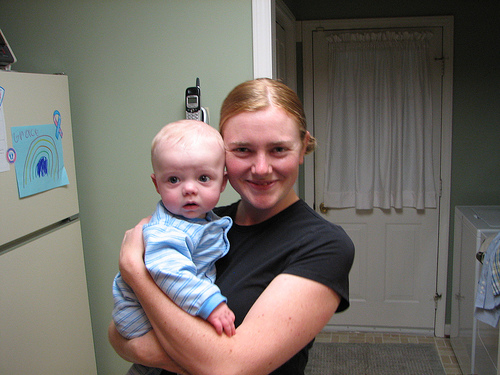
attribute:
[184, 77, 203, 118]
telephone — grey, landline, silver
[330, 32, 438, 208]
curtain — white, beige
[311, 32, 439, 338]
door — white, beige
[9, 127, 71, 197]
drawing — rainbow, blue, child's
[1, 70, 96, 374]
fridge — decorated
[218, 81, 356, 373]
woman — smiling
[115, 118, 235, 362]
baby — startled, pale, blonde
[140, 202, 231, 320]
onesie — blue, stripped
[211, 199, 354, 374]
shirt — black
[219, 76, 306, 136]
hair — blonde, tied, parted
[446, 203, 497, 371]
washer — front-loading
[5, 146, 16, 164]
magnet — round